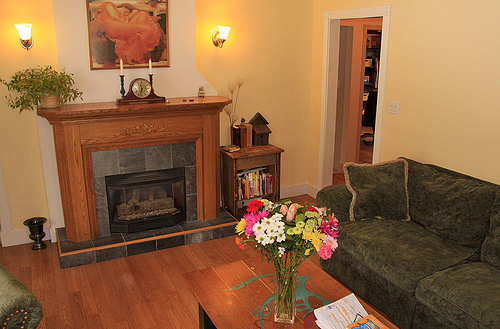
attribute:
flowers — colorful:
[240, 192, 336, 259]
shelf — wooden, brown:
[225, 145, 290, 228]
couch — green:
[327, 152, 498, 313]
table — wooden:
[203, 266, 355, 325]